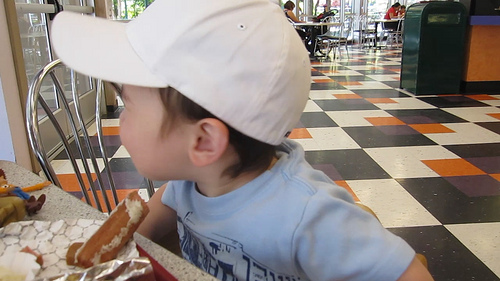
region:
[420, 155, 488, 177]
orange tile on the floor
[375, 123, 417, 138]
purple tile on the floor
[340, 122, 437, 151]
black tile on the floor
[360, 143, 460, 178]
white tile on the floor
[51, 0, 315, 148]
white hat on the kid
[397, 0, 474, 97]
black trash can behind the kid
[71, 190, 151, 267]
hot dog in front of the kid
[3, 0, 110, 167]
silver doors with windows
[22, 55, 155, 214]
silver chair near the kid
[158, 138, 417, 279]
blue shirt on the kid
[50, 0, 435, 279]
Young boy sitting at a table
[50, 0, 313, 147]
White baseball cap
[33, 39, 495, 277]
Black, white, purple and orange square tiled floor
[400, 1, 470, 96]
Metal green trashcan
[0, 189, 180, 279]
Red food tray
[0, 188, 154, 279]
Partially eaten hot dogs on foil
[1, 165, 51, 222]
Toy people figurines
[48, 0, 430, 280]
Boy wearing a hat and blue shirt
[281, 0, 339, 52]
Woman feeding a baby in a stroller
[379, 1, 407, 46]
Two people sitting at a diner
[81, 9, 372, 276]
This is a person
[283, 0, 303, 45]
This is a person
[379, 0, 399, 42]
This is a person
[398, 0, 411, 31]
This is a person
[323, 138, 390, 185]
This is a tile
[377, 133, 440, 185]
This is a tile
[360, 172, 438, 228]
This is a tile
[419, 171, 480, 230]
This is a tile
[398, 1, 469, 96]
green metal trash can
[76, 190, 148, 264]
hotdog weenie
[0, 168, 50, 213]
toy sitting on table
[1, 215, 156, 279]
hot dog wrapper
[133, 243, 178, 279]
red food tray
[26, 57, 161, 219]
shiny grey metal chair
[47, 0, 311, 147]
white baseball cap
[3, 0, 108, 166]
metal and glass doors in a restaurant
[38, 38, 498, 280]
multi-colored tile on floor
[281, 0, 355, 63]
two people sitting at a restaurant table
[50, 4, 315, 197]
The little boy is wearing a hat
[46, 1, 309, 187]
The boy is wearing a white hat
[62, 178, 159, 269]
A half-eaten hotdog is on the tray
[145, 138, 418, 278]
The boy is wearing a light blue shirt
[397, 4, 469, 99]
The trashcan is painted green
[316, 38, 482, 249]
The floor is checkered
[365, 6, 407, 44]
A woman in a red shirt sits at a table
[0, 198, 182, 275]
Food is on a tray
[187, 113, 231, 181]
The little boy's left ear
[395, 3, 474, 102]
The trashcan is made of metal